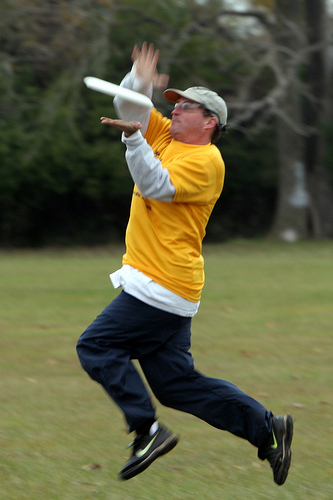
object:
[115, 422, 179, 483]
shoes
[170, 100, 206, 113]
eyeglasses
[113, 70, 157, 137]
sleeve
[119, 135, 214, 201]
sleeve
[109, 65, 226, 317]
teeshirt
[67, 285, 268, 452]
pants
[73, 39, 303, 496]
man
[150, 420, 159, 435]
socks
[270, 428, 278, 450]
check mark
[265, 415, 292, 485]
sneaker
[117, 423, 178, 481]
sneaker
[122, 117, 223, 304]
t-shirt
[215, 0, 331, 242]
tree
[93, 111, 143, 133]
hands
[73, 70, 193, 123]
frisbee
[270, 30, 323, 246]
trunk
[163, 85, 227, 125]
hat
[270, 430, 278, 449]
stripe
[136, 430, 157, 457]
stripe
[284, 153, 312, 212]
target